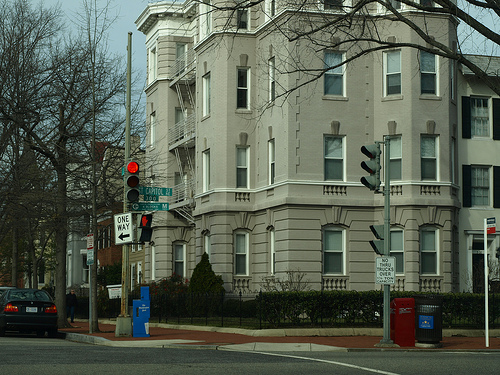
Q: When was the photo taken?
A: Daytime.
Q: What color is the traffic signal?
A: Red.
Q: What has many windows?
A: Building.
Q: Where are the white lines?
A: Street.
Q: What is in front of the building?
A: Shrubs.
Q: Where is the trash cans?
A: Beside pole.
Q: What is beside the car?
A: Tree.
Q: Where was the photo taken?
A: Outside on the corner of a one way street.